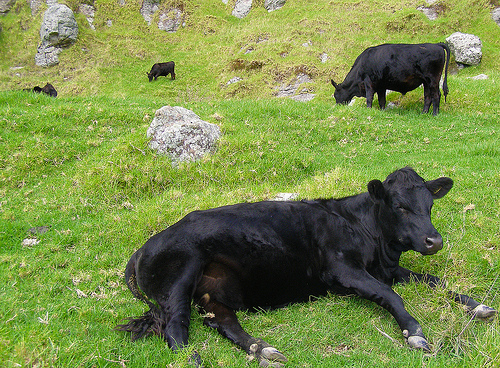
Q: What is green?
A: The grass.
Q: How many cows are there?
A: Four.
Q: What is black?
A: The cows.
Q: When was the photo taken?
A: Day time.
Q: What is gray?
A: The rocks.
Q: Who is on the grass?
A: The cows.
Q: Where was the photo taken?
A: In a field.